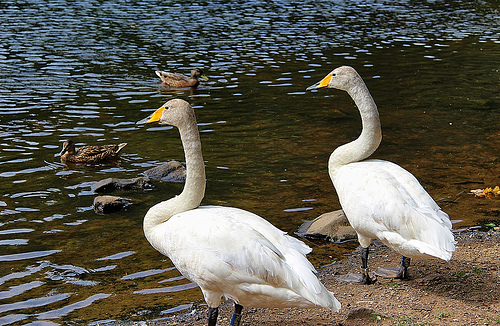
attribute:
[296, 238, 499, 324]
ground — covered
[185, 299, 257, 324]
legs — black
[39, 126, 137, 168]
duck — brown, floating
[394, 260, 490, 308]
shadow — of duck 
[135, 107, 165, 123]
beak — yellow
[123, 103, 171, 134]
beak — orange, black 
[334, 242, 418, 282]
feet — black , goose feet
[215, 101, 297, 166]
water — brown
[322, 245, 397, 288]
webbed feet — webbed 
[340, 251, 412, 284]
feet — black webbed, duck feet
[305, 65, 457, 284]
duck — large, white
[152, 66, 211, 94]
duck — brown 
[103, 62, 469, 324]
geese — white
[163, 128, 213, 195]
neck — long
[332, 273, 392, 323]
dirt — brown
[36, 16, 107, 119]
stones — large